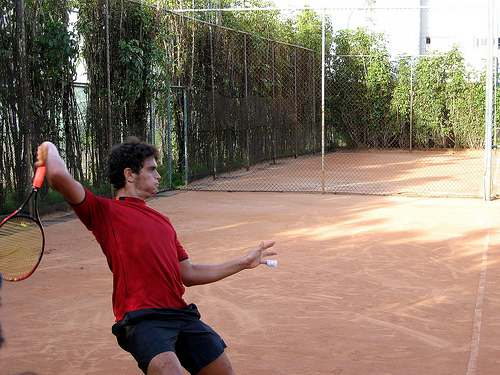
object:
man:
[31, 140, 286, 375]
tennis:
[0, 124, 73, 294]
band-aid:
[264, 259, 276, 269]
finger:
[263, 259, 266, 265]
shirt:
[63, 180, 201, 324]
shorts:
[107, 299, 239, 375]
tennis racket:
[0, 146, 49, 289]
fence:
[203, 53, 318, 118]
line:
[469, 267, 493, 317]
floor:
[338, 240, 396, 258]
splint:
[59, 0, 129, 111]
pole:
[313, 0, 334, 197]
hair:
[120, 135, 144, 161]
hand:
[235, 235, 288, 276]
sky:
[362, 16, 408, 37]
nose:
[152, 172, 162, 183]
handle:
[21, 156, 50, 192]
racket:
[0, 145, 53, 295]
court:
[224, 201, 345, 231]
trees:
[81, 27, 156, 118]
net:
[218, 84, 437, 157]